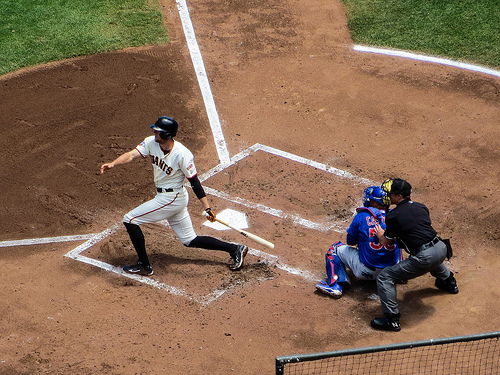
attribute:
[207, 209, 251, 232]
home plate — white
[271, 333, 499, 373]
fence — black, metal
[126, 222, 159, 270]
socks — black, long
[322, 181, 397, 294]
catcher — crouched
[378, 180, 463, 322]
umpire — squatting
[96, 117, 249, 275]
player — twisted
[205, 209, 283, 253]
bat — white, wooden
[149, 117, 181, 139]
helmet — protective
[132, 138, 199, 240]
uniform — white, black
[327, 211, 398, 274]
uniform — blue, red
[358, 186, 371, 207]
mask — blue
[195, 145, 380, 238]
batters box — white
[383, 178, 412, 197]
hat — black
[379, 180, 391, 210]
mask — yellow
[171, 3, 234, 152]
line — white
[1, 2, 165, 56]
grass — green